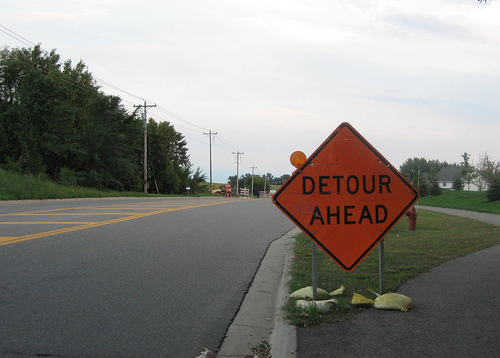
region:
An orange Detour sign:
[272, 119, 420, 271]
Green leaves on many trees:
[0, 40, 212, 195]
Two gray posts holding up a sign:
[306, 236, 388, 300]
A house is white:
[433, 158, 493, 198]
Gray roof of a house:
[433, 161, 475, 183]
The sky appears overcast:
[1, 3, 497, 183]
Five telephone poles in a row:
[134, 96, 271, 198]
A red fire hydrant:
[399, 204, 422, 234]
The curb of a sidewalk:
[261, 233, 302, 355]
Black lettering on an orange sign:
[297, 169, 314, 203]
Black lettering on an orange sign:
[312, 172, 332, 198]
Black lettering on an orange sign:
[328, 169, 343, 196]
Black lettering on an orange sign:
[340, 171, 360, 199]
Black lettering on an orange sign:
[360, 170, 377, 205]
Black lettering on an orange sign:
[375, 166, 395, 196]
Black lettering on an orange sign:
[300, 201, 327, 233]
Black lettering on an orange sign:
[320, 202, 343, 229]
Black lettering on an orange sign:
[342, 202, 357, 232]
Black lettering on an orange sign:
[355, 201, 378, 236]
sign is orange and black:
[268, 115, 419, 274]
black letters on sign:
[300, 172, 396, 225]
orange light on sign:
[285, 150, 310, 168]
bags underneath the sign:
[288, 278, 415, 316]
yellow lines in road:
[0, 192, 247, 257]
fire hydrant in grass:
[403, 203, 422, 231]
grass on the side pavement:
[240, 335, 269, 357]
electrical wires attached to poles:
[0, 14, 282, 182]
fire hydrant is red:
[408, 201, 420, 228]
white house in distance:
[435, 160, 493, 192]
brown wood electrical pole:
[134, 99, 155, 196]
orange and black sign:
[276, 122, 417, 271]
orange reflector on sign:
[290, 151, 306, 169]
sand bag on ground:
[374, 292, 411, 313]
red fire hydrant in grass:
[407, 208, 419, 231]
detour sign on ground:
[273, 122, 418, 305]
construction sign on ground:
[273, 122, 418, 317]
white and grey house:
[437, 164, 490, 193]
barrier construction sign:
[239, 187, 250, 199]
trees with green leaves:
[1, 43, 193, 197]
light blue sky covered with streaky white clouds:
[1, 3, 496, 178]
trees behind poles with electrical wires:
[0, 15, 270, 205]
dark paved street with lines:
[0, 190, 260, 355]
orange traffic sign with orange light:
[270, 120, 415, 270]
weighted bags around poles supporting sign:
[285, 196, 415, 316]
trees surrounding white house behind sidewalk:
[385, 146, 495, 227]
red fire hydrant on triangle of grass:
[295, 122, 490, 307]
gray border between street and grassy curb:
[192, 195, 302, 355]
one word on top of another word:
[291, 170, 393, 226]